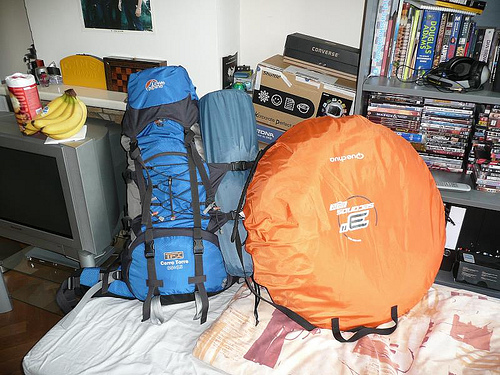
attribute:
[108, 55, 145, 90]
chess board — wood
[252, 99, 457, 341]
orange bag — large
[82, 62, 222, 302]
blue backpack — large, weather resistant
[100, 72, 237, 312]
blue backpack — large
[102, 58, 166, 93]
checker set — black, brown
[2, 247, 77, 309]
table — two level, glass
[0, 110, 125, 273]
television — medium, silver, grey, small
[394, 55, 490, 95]
headset — grey, black, wired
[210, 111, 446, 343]
cone — orange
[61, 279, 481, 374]
bed — small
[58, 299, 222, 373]
sheet — white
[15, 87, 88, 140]
bananas — yellow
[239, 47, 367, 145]
box — brown, black, cardboard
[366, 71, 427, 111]
shelf — grey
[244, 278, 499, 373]
design — abstract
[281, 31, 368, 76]
box — brown, black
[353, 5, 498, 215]
dvds — stack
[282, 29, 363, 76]
shoe box — black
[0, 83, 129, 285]
set — television